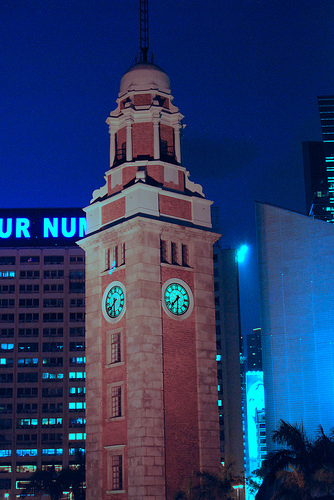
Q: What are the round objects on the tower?
A: Clocks.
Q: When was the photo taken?
A: Night.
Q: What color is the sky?
A: Blue.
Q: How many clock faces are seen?
A: Two.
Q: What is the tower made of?
A: Bricks.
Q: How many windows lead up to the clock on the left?
A: Three.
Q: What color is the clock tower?
A: Red.